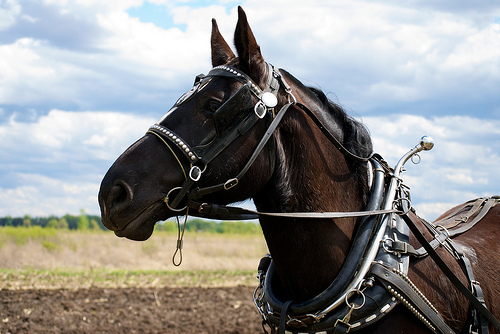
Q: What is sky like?
A: Cloudy.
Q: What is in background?
A: Field.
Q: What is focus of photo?
A: Brown horse.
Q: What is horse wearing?
A: Straps.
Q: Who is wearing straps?
A: The horse.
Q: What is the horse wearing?
A: Straps.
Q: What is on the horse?
A: Straps.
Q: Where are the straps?
A: On the horse.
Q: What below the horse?
A: Dirt.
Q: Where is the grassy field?
A: Next to the horse.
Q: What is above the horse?
A: The sky.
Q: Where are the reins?
A: On the horse.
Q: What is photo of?
A: A horse near a grassy field.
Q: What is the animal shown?
A: Horse.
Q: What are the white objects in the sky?
A: Clouds.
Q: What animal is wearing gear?
A: Horse.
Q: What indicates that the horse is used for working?
A: Yoke and gear.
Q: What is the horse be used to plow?
A: Field.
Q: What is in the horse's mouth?
A: Bit.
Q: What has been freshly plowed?
A: Dirt.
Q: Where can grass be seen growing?
A: Background.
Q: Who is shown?
A: A horse.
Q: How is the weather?
A: Cloudy.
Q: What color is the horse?
A: Brown.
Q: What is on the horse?
A: A harness.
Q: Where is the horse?
A: In a field.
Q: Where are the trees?
A: At the back of the field.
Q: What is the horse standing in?
A: Dirt.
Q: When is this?
A: During the day.